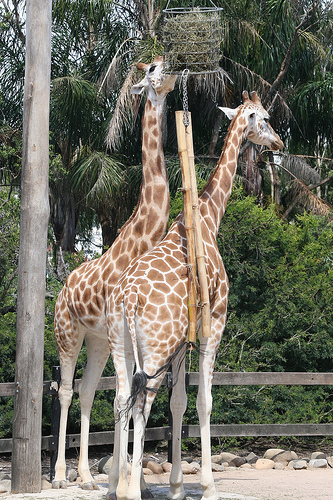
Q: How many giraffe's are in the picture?
A: Two.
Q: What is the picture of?
A: Giraffe's.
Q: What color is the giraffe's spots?
A: Brown.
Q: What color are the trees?
A: Green.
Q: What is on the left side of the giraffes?
A: A pole.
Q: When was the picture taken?
A: During the day.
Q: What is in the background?
A: Trees.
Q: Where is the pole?
A: Left side of picture.